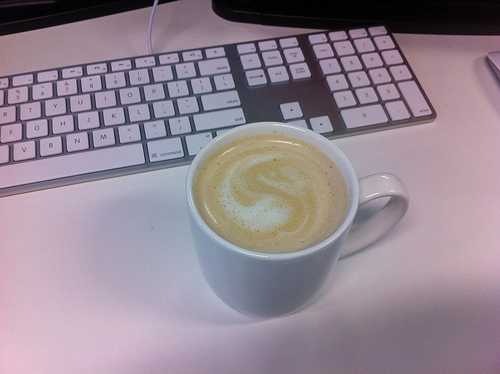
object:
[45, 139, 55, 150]
letter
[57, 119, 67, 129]
letter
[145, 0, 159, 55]
cord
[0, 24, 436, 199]
keyboard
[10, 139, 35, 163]
v key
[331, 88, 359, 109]
key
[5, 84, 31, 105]
key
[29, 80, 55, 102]
key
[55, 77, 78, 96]
key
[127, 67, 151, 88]
key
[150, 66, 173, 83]
key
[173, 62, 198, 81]
key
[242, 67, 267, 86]
key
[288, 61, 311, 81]
key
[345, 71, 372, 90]
key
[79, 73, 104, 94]
key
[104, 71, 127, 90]
key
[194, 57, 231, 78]
key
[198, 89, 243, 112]
key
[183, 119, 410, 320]
cup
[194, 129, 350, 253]
liquid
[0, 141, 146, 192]
keys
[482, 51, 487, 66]
corner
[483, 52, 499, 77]
mouse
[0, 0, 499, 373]
desk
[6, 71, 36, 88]
key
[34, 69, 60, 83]
key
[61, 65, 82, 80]
key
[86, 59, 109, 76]
key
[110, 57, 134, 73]
key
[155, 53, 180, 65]
key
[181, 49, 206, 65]
key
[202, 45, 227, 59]
key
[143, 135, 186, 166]
command key